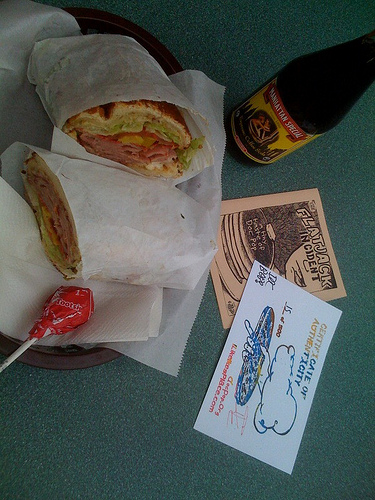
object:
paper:
[0, 0, 227, 377]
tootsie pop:
[3, 281, 94, 396]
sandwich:
[9, 145, 82, 281]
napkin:
[0, 164, 167, 348]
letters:
[295, 379, 301, 388]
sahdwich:
[28, 34, 195, 185]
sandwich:
[19, 13, 255, 319]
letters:
[227, 376, 233, 385]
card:
[193, 259, 343, 475]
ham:
[86, 130, 175, 162]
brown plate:
[1, 2, 199, 373]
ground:
[303, 131, 329, 171]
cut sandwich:
[18, 30, 204, 286]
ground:
[298, 64, 328, 86]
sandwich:
[68, 110, 197, 167]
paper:
[73, 50, 131, 97]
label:
[228, 75, 320, 166]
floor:
[171, 126, 190, 146]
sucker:
[2, 282, 101, 380]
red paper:
[24, 280, 101, 347]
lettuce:
[182, 142, 203, 165]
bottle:
[227, 27, 374, 169]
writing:
[267, 84, 305, 140]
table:
[1, 0, 374, 498]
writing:
[275, 298, 290, 341]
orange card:
[211, 187, 348, 330]